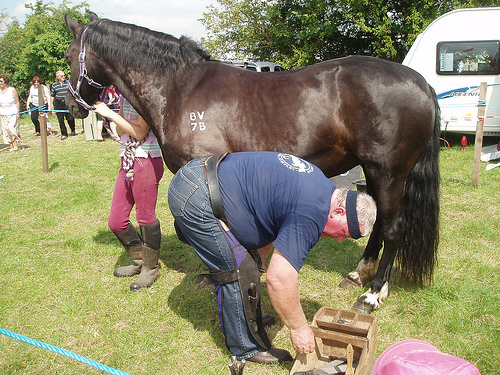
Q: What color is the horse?
A: Brown.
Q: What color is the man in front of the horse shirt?
A: Blue.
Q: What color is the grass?
A: Green.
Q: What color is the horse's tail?
A: Black.